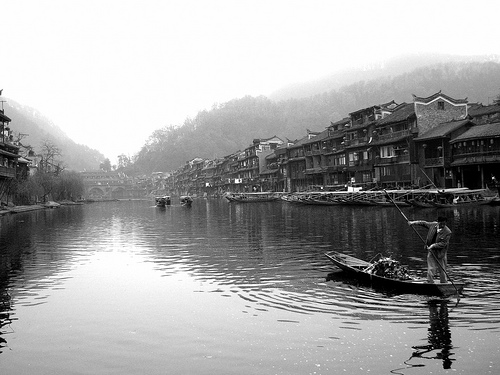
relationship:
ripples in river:
[83, 196, 177, 235] [0, 196, 499, 374]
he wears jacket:
[404, 213, 452, 286] [395, 199, 465, 257]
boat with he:
[291, 169, 477, 302] [404, 213, 452, 286]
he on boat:
[404, 213, 452, 286] [291, 169, 477, 302]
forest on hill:
[145, 70, 318, 173] [49, 84, 338, 212]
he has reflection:
[404, 213, 452, 286] [417, 290, 471, 373]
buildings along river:
[163, 81, 490, 211] [18, 185, 429, 330]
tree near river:
[36, 130, 62, 184] [18, 185, 429, 330]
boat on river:
[291, 169, 477, 302] [18, 185, 429, 330]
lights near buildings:
[202, 136, 357, 178] [163, 81, 490, 211]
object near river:
[245, 177, 488, 240] [18, 185, 429, 330]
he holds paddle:
[404, 213, 452, 286] [397, 230, 481, 306]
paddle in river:
[397, 230, 481, 306] [0, 196, 499, 374]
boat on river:
[291, 169, 477, 302] [0, 196, 499, 374]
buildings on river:
[163, 81, 490, 211] [0, 196, 499, 374]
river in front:
[0, 196, 499, 374] [220, 179, 403, 217]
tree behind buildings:
[36, 130, 62, 184] [163, 81, 490, 211]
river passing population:
[18, 185, 429, 330] [141, 168, 499, 317]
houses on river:
[163, 81, 490, 211] [18, 185, 429, 330]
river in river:
[0, 196, 499, 374] [18, 185, 429, 330]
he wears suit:
[404, 213, 452, 286] [407, 221, 452, 266]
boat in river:
[291, 169, 477, 302] [18, 185, 429, 330]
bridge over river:
[74, 163, 167, 204] [18, 185, 429, 330]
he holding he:
[383, 171, 476, 299] [404, 213, 452, 286]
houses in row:
[121, 131, 473, 187] [163, 81, 490, 211]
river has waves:
[0, 196, 499, 374] [85, 192, 166, 266]